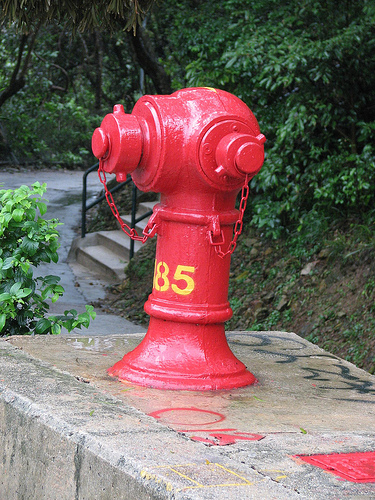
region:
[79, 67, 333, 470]
a red fire hydrant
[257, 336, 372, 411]
black graffiti on a cement platform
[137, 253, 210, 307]
yellow paint on a fire hydrant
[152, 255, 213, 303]
a painted number on a fire hydrant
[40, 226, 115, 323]
a sidewalk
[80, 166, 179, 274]
a staircase that goes past the bushes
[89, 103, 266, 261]
stoppers on a fire hydrant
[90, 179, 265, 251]
red chains on a fire hydrant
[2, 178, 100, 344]
a green bush near a fire hydrant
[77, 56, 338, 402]
a brightly colored fire hydrant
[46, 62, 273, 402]
the hydrant is red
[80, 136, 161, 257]
chain attached to the hydrant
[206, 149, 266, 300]
chain attached to the hydrant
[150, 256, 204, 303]
85 stenciled in yellow paint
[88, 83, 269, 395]
red fire hydrant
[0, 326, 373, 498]
concrete platform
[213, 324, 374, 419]
graffiti written with black paint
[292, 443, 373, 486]
metal plate painted red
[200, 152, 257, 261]
chain attached to the valve cover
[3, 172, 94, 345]
shrub with green leaves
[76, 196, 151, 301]
set of concrete stairs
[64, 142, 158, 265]
black, metal railings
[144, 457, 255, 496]
yellow rectangle painted on the platform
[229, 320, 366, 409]
some black graffiti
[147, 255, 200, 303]
a number written in spray paint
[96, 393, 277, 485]
a crack in the concrete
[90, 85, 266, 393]
a bright red hydrant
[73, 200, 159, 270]
a few cement stairs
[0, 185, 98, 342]
a full green plant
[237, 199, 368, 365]
a plant covered hillside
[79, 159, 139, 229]
a black metal hand rail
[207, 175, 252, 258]
a bright red chain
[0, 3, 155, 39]
a few drooping leaves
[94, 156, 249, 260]
The fire hydrant has red chains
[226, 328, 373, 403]
black graffiti on the cement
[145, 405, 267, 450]
red graffiti on the cement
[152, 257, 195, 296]
yellow number 85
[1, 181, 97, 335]
green leaves beside the cement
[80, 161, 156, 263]
the railing is black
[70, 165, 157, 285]
stairs between the railings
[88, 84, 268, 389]
the fire hydrant is shiny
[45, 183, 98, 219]
a small puddle of water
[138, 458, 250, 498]
a yellow marking on the cement